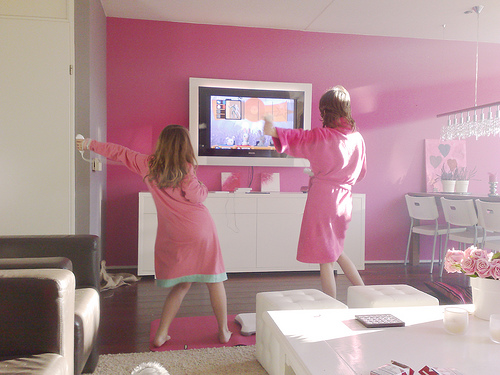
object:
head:
[317, 86, 354, 130]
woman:
[262, 86, 366, 300]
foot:
[151, 312, 232, 349]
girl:
[76, 124, 232, 348]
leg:
[152, 276, 236, 346]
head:
[142, 123, 203, 188]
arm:
[76, 132, 151, 177]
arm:
[263, 116, 319, 157]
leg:
[314, 245, 370, 304]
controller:
[75, 126, 103, 174]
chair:
[0, 233, 102, 371]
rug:
[149, 312, 448, 351]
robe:
[85, 137, 229, 287]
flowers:
[443, 247, 499, 282]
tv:
[187, 75, 315, 168]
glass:
[437, 303, 470, 338]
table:
[252, 303, 500, 374]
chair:
[403, 191, 468, 274]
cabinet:
[137, 192, 364, 277]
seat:
[252, 286, 354, 374]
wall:
[106, 15, 500, 271]